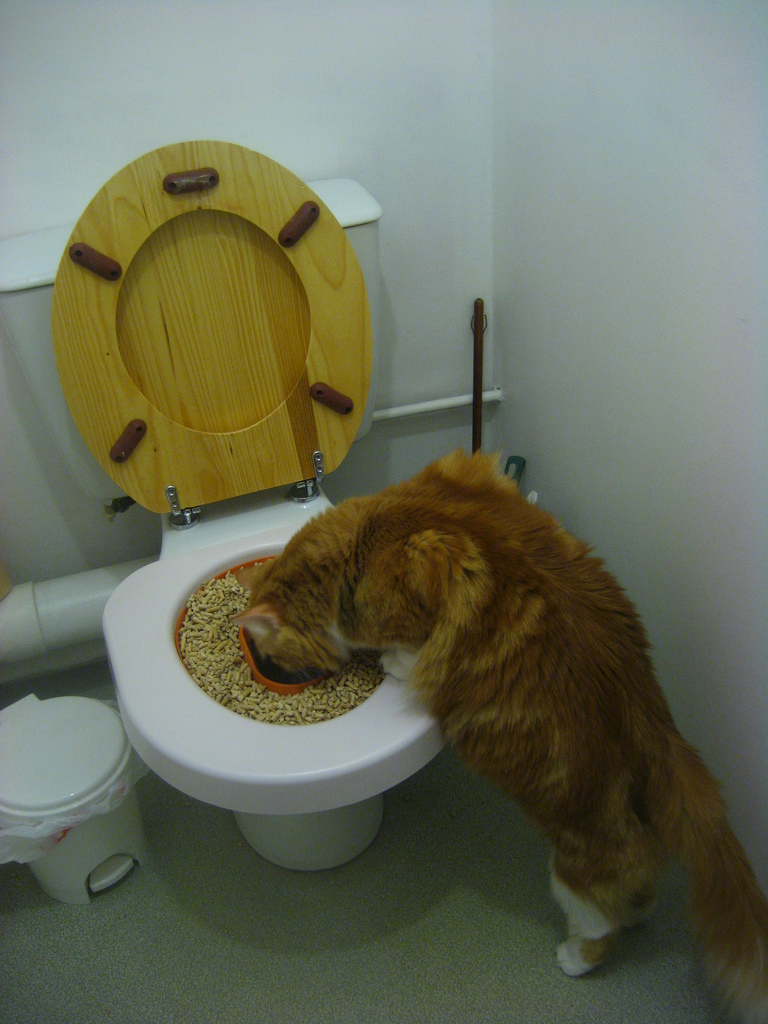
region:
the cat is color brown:
[227, 434, 765, 1022]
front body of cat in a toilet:
[0, 123, 517, 933]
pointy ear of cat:
[223, 591, 288, 641]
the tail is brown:
[676, 787, 765, 1022]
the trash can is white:
[0, 681, 163, 921]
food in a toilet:
[167, 536, 397, 736]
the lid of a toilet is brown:
[39, 127, 395, 535]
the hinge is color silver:
[154, 477, 205, 536]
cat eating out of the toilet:
[51, 142, 763, 1019]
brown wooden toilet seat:
[51, 137, 363, 512]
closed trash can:
[0, 687, 134, 899]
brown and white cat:
[242, 450, 763, 1019]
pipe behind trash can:
[0, 557, 155, 899]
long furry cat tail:
[682, 732, 765, 1021]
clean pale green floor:
[1, 652, 695, 1022]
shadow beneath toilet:
[51, 139, 458, 946]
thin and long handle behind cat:
[472, 299, 482, 453]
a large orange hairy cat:
[250, 486, 745, 968]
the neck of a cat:
[305, 532, 397, 626]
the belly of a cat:
[421, 626, 607, 832]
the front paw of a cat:
[359, 631, 433, 694]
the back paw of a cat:
[524, 894, 627, 994]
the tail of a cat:
[669, 802, 765, 986]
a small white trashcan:
[2, 672, 146, 911]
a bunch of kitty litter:
[197, 598, 245, 668]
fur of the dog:
[520, 659, 606, 770]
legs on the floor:
[538, 894, 638, 1022]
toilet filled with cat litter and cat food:
[44, 141, 458, 874]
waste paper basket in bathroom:
[0, 692, 152, 911]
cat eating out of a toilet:
[106, 444, 764, 1022]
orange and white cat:
[226, 450, 764, 1022]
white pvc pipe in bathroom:
[3, 551, 158, 685]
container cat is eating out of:
[236, 604, 325, 693]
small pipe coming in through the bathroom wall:
[373, 385, 504, 426]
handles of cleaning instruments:
[467, 297, 540, 506]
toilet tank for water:
[1, 174, 385, 503]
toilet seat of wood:
[46, 137, 376, 518]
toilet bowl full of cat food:
[54, 140, 479, 870]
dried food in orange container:
[174, 555, 386, 728]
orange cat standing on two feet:
[235, 445, 767, 1011]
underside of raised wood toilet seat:
[50, 139, 372, 515]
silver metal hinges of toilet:
[164, 450, 324, 528]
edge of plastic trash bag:
[0, 742, 150, 862]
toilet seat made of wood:
[51, 137, 377, 522]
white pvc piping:
[2, 559, 138, 674]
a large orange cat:
[241, 435, 758, 986]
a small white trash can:
[4, 685, 148, 917]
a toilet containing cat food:
[102, 498, 465, 878]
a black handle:
[463, 291, 497, 455]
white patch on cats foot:
[542, 848, 616, 984]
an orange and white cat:
[233, 447, 761, 1021]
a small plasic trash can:
[0, 692, 147, 901]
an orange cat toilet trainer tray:
[167, 544, 405, 727]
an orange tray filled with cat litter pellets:
[173, 550, 392, 726]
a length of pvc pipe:
[0, 551, 154, 666]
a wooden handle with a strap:
[467, 294, 493, 457]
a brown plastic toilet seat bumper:
[162, 166, 221, 198]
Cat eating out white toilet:
[238, 567, 748, 993]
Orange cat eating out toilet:
[249, 498, 732, 988]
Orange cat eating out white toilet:
[261, 521, 741, 998]